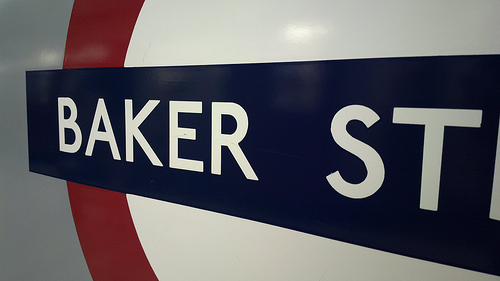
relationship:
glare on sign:
[11, 10, 363, 156] [14, 40, 497, 265]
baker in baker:
[41, 80, 281, 184] [57, 97, 259, 181]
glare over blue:
[38, 20, 322, 111] [24, 54, 499, 275]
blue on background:
[24, 54, 499, 275] [2, 2, 497, 279]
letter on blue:
[55, 95, 82, 155] [24, 54, 499, 275]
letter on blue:
[390, 104, 484, 214] [24, 54, 499, 275]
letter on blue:
[210, 99, 261, 184] [24, 54, 499, 275]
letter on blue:
[168, 100, 202, 175] [24, 54, 499, 275]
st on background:
[321, 98, 486, 215] [25, 70, 499, 95]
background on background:
[58, 98, 482, 213] [31, 72, 483, 242]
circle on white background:
[61, 0, 157, 281] [2, 0, 497, 278]